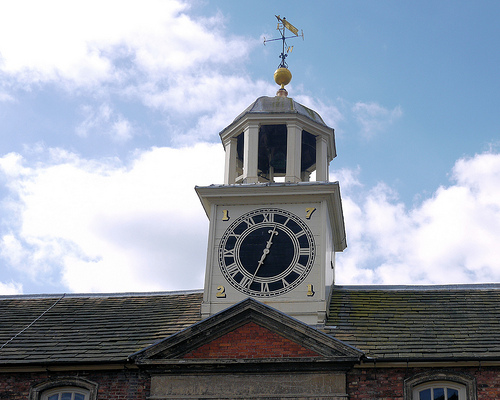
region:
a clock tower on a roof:
[184, 5, 345, 309]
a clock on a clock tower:
[212, 205, 327, 297]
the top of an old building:
[0, 284, 498, 398]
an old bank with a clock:
[0, 10, 498, 397]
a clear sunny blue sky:
[4, 7, 498, 289]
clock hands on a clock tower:
[247, 223, 284, 284]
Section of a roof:
[4, 298, 69, 323]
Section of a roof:
[45, 306, 121, 353]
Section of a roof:
[367, 296, 442, 336]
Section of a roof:
[465, 285, 498, 356]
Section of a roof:
[422, 283, 474, 360]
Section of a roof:
[380, 280, 441, 363]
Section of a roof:
[341, 281, 415, 370]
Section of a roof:
[128, 287, 205, 372]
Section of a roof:
[92, 288, 167, 364]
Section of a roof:
[37, 290, 121, 361]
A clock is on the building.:
[195, 179, 335, 324]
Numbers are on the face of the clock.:
[210, 197, 327, 305]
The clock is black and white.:
[208, 201, 325, 308]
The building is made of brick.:
[2, 291, 498, 399]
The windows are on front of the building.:
[401, 372, 471, 399]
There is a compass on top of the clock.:
[257, 12, 314, 96]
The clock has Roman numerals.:
[211, 198, 323, 301]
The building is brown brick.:
[1, 291, 492, 399]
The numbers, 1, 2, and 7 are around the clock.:
[202, 191, 332, 313]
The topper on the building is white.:
[202, 12, 340, 322]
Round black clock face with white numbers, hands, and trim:
[218, 206, 317, 298]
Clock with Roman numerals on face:
[217, 205, 317, 298]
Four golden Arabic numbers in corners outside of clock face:
[216, 206, 316, 298]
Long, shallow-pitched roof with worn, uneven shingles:
[1, 282, 498, 365]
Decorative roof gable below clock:
[127, 297, 366, 371]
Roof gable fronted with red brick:
[123, 297, 366, 372]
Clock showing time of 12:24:
[217, 205, 317, 298]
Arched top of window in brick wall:
[403, 368, 477, 399]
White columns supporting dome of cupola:
[223, 122, 330, 182]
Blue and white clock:
[218, 208, 330, 298]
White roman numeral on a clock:
[258, 207, 278, 230]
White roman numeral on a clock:
[278, 208, 293, 228]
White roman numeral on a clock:
[290, 221, 305, 246]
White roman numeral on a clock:
[294, 245, 314, 259]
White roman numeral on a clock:
[289, 261, 306, 276]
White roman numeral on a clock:
[275, 271, 290, 292]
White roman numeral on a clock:
[255, 276, 271, 296]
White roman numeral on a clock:
[237, 268, 253, 290]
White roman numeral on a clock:
[218, 257, 243, 278]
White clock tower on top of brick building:
[193, 13, 347, 328]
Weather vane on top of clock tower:
[261, 13, 306, 87]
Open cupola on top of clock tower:
[218, 87, 339, 184]